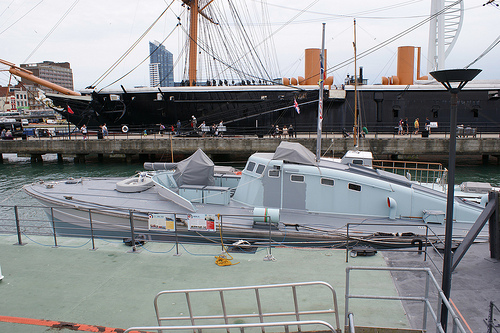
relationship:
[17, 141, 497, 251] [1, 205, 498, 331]
boat in dock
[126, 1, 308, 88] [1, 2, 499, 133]
mast on ship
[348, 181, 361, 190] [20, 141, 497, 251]
windows on boat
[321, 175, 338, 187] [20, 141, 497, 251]
windows on boat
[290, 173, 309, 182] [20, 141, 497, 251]
windows on boat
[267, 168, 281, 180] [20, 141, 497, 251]
windows on boat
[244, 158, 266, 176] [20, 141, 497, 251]
windows on boat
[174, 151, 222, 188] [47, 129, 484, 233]
gray covers over part of boat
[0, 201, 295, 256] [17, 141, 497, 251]
fence beside boat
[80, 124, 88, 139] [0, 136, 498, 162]
person on dock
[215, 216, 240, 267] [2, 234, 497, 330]
rope on ground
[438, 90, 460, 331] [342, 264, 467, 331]
post by rail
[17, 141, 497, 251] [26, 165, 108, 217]
boat has bow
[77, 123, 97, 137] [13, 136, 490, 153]
person on dock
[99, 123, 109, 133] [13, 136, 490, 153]
person on dock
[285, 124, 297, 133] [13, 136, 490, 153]
person on dock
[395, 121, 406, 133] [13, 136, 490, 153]
person on dock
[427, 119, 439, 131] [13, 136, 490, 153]
person on dock